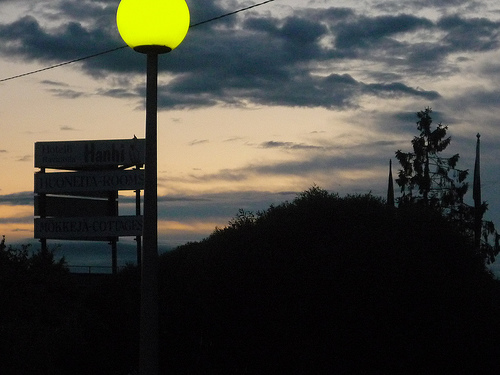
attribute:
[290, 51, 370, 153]
sky — cloudy, evening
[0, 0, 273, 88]
cable — power cable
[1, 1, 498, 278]
sky — orange, blue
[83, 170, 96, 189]
letter — black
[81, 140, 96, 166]
letter — black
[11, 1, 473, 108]
cloud — dark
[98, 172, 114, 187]
letter — black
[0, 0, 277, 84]
line — electrical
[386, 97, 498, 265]
tree — tall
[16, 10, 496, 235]
sky — orange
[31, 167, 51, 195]
letter — black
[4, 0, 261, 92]
electrical wire — overhead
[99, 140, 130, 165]
letter — black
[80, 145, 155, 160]
letter — black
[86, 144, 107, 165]
letter — black